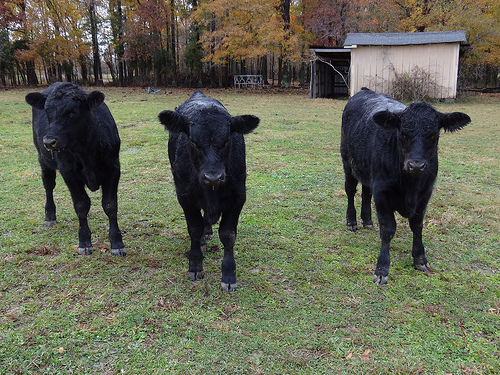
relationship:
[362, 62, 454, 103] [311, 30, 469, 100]
dead foliage against shed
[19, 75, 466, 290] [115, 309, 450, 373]
cows standing in field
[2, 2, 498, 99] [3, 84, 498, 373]
trees lining property